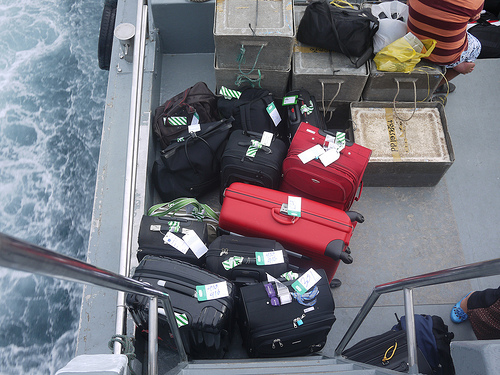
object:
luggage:
[219, 129, 286, 204]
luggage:
[221, 85, 287, 129]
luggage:
[234, 275, 339, 359]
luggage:
[136, 211, 217, 267]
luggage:
[280, 120, 373, 210]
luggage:
[217, 181, 365, 289]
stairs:
[0, 227, 500, 372]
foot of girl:
[455, 60, 476, 77]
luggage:
[365, 58, 443, 102]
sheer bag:
[370, 31, 436, 73]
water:
[1, 1, 108, 375]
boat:
[1, 2, 500, 374]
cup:
[112, 22, 135, 63]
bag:
[295, 0, 379, 68]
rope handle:
[152, 214, 178, 224]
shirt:
[407, 1, 484, 64]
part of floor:
[163, 49, 499, 354]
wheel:
[339, 250, 355, 266]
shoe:
[450, 297, 469, 325]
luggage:
[149, 80, 219, 145]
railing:
[0, 214, 188, 375]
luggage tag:
[253, 248, 287, 266]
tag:
[337, 128, 345, 148]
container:
[152, 3, 212, 55]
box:
[348, 97, 455, 189]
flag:
[247, 140, 260, 158]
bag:
[145, 194, 221, 226]